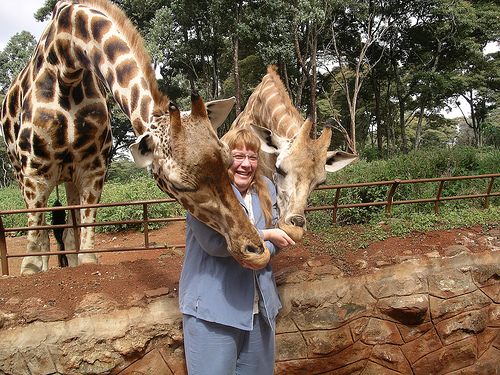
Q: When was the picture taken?
A: Daytime.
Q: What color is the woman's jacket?
A: Blue.